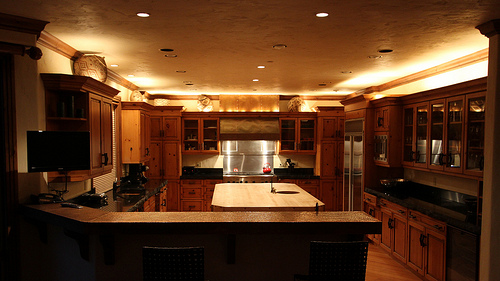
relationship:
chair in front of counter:
[137, 230, 220, 280] [41, 184, 395, 274]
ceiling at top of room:
[11, 0, 493, 96] [0, 0, 499, 277]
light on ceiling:
[99, 52, 123, 69] [230, 18, 345, 78]